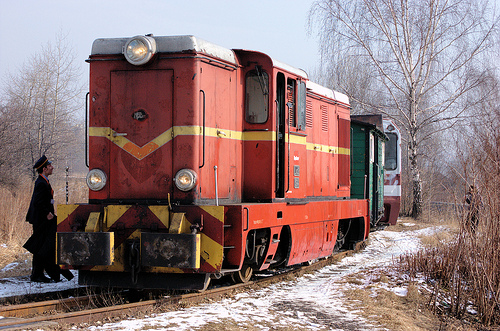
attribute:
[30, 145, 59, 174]
hat — red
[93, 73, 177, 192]
train — red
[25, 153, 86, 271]
conductor — beside, looking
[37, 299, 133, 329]
rail — silver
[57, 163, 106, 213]
house — small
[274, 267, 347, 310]
snow — white, patchy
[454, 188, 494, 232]
person — standing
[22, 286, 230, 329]
railway — tracks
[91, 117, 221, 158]
line — yellow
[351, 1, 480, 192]
tree — growing, bare, leafless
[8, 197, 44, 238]
grass — dry, brown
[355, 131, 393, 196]
car — green, orange, rust colored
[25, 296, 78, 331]
tracks — metal, railroad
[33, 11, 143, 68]
sky — greyish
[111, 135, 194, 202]
heart — red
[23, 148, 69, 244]
man — standing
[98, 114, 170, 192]
design — heart